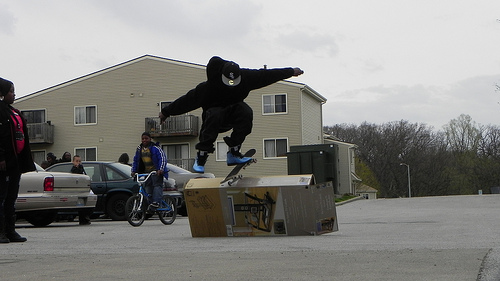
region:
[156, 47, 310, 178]
person on a skate board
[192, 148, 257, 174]
bright blue shoes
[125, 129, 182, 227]
kid on a short bike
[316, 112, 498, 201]
dense grouping of leafless trees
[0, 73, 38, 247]
person wearing black pants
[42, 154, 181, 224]
dark blue parked car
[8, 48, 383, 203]
tan coloured apartment buildings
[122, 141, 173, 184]
puffy blue jacket with white stripes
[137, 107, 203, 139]
small weathered wooden porch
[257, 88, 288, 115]
two paned white framed window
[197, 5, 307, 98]
the head of a man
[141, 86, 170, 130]
the hand of a man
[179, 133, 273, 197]
a man wearing shoes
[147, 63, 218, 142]
the arm of a man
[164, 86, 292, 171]
the legs of a man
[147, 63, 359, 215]
a man on a skateboard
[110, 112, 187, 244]
a boy on a bike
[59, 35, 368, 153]
a house in the bacground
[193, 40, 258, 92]
a man wearing a hat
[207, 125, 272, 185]
the wheels on a skateboard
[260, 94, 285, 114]
the window on the building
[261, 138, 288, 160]
the window on the building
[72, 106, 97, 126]
the window on the building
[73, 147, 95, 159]
the window on the building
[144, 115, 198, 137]
the balcony on the building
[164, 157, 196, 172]
the balcony on the building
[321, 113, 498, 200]
the trees behind the building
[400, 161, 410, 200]
the street light in front of the trees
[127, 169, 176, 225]
the bicycle under the boy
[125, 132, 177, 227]
the boy on the bicycle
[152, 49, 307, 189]
A skateboarder in the air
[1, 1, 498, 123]
The sky appears overcast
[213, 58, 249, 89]
A hat is black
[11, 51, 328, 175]
A house behind the cars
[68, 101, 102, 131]
Window on a house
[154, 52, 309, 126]
Skateboarder has two arms raised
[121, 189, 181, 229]
Two round bicycle wheels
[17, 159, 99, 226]
The back of a car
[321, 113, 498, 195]
Trees are in the background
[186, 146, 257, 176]
Black laces on blue sneakers